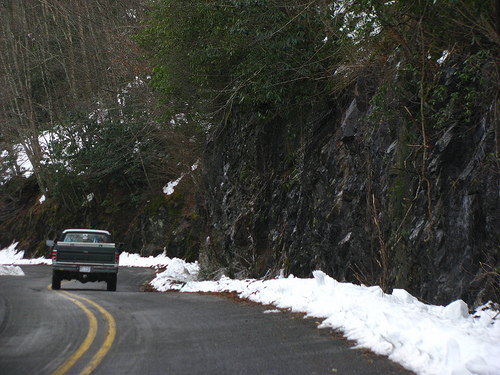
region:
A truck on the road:
[48, 219, 125, 291]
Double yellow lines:
[49, 289, 118, 370]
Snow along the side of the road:
[299, 265, 499, 372]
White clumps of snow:
[315, 269, 498, 361]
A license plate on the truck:
[76, 258, 94, 280]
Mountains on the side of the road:
[228, 50, 498, 287]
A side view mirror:
[40, 236, 57, 248]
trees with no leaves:
[0, 0, 114, 112]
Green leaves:
[144, 4, 307, 93]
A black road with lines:
[0, 273, 265, 373]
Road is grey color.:
[115, 310, 275, 370]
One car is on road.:
[41, 217, 128, 302]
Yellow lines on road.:
[30, 305, 126, 352]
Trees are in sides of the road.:
[100, 56, 435, 221]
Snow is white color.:
[301, 272, 441, 347]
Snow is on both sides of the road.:
[260, 280, 430, 370]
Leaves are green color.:
[175, 25, 310, 85]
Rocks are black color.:
[425, 175, 475, 275]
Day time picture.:
[15, 26, 465, 366]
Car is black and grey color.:
[49, 227, 125, 292]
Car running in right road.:
[42, 223, 131, 300]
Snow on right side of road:
[298, 271, 498, 368]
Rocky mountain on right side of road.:
[149, 29, 496, 261]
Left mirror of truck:
[37, 232, 58, 252]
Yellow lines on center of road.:
[37, 278, 123, 370]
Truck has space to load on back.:
[41, 221, 125, 296]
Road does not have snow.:
[1, 298, 281, 373]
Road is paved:
[7, 300, 262, 366]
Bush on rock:
[125, 0, 257, 126]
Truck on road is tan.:
[37, 219, 127, 297]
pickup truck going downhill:
[7, 198, 194, 370]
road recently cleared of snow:
[76, 282, 421, 374]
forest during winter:
[24, 9, 185, 220]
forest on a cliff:
[175, 19, 475, 291]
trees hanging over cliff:
[148, 5, 338, 274]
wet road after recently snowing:
[11, 284, 467, 372]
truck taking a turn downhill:
[7, 46, 160, 356]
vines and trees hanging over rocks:
[241, 2, 497, 287]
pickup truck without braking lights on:
[9, 200, 200, 362]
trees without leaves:
[4, 7, 42, 205]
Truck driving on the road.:
[49, 224, 119, 289]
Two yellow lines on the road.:
[45, 279, 118, 374]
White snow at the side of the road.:
[272, 268, 498, 374]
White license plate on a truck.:
[77, 264, 91, 274]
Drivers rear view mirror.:
[43, 236, 53, 248]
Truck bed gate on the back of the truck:
[57, 243, 114, 263]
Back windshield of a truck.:
[60, 229, 110, 246]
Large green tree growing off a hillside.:
[136, 0, 343, 125]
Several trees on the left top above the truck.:
[1, 1, 160, 193]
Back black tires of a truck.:
[50, 271, 117, 290]